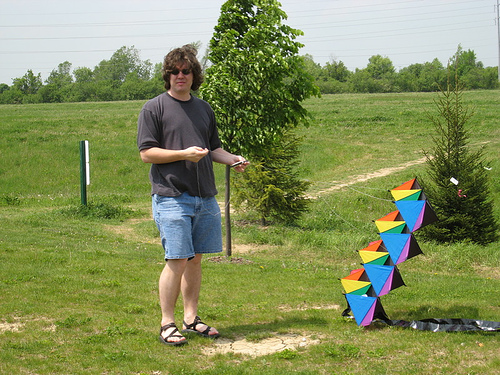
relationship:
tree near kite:
[415, 67, 498, 244] [334, 173, 441, 328]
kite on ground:
[339, 177, 498, 352] [0, 90, 498, 371]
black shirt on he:
[136, 90, 221, 200] [135, 42, 251, 346]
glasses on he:
[171, 62, 200, 84] [135, 42, 251, 346]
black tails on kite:
[381, 314, 498, 338] [339, 177, 498, 352]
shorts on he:
[146, 190, 223, 257] [135, 42, 251, 346]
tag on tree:
[436, 162, 477, 202] [403, 54, 498, 270]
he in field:
[135, 42, 251, 346] [16, 274, 394, 371]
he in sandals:
[135, 42, 251, 346] [150, 310, 220, 350]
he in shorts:
[135, 42, 251, 346] [151, 192, 223, 258]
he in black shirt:
[135, 42, 251, 346] [136, 90, 221, 200]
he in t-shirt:
[135, 42, 251, 346] [136, 39, 236, 344]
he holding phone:
[135, 42, 251, 346] [224, 149, 250, 173]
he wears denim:
[135, 42, 251, 346] [152, 192, 222, 257]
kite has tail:
[337, 175, 499, 337] [391, 308, 484, 329]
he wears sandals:
[128, 45, 251, 346] [159, 317, 212, 343]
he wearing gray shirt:
[128, 45, 251, 346] [133, 90, 240, 212]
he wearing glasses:
[135, 42, 251, 346] [171, 68, 195, 78]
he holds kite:
[135, 42, 251, 346] [339, 177, 498, 352]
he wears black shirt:
[135, 42, 251, 346] [136, 90, 221, 200]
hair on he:
[161, 52, 205, 83] [135, 42, 251, 346]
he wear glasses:
[135, 42, 251, 346] [163, 64, 195, 80]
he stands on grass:
[135, 42, 251, 346] [2, 86, 497, 373]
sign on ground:
[80, 140, 89, 185] [0, 90, 498, 371]